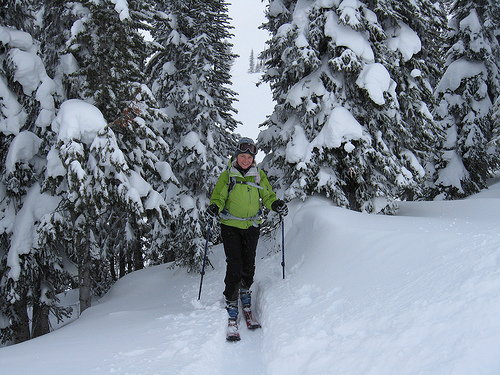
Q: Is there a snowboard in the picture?
A: No, there are no snowboards.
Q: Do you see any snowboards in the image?
A: No, there are no snowboards.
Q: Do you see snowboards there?
A: No, there are no snowboards.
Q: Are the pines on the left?
A: Yes, the pines are on the left of the image.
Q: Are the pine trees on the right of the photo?
A: No, the pine trees are on the left of the image.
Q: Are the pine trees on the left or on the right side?
A: The pine trees are on the left of the image.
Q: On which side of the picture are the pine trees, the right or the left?
A: The pine trees are on the left of the image.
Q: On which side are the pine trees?
A: The pine trees are on the left of the image.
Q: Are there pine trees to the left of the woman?
A: Yes, there are pine trees to the left of the woman.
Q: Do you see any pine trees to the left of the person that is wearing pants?
A: Yes, there are pine trees to the left of the woman.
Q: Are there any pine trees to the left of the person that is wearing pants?
A: Yes, there are pine trees to the left of the woman.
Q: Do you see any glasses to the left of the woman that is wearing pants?
A: No, there are pine trees to the left of the woman.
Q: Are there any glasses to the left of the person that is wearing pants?
A: No, there are pine trees to the left of the woman.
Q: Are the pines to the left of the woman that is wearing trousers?
A: Yes, the pines are to the left of the woman.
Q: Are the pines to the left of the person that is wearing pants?
A: Yes, the pines are to the left of the woman.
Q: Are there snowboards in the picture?
A: No, there are no snowboards.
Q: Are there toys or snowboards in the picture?
A: No, there are no snowboards or toys.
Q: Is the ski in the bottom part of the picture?
A: Yes, the ski is in the bottom of the image.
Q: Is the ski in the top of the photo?
A: No, the ski is in the bottom of the image.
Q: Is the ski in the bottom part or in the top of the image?
A: The ski is in the bottom of the image.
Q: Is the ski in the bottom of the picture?
A: Yes, the ski is in the bottom of the image.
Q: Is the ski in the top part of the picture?
A: No, the ski is in the bottom of the image.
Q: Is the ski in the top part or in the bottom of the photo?
A: The ski is in the bottom of the image.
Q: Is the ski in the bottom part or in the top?
A: The ski is in the bottom of the image.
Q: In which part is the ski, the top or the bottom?
A: The ski is in the bottom of the image.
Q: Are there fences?
A: No, there are no fences.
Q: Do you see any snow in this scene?
A: Yes, there is snow.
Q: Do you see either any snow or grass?
A: Yes, there is snow.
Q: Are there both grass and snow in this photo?
A: No, there is snow but no grass.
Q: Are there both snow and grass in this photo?
A: No, there is snow but no grass.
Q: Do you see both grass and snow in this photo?
A: No, there is snow but no grass.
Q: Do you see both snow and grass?
A: No, there is snow but no grass.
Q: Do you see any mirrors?
A: No, there are no mirrors.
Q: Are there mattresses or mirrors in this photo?
A: No, there are no mirrors or mattresses.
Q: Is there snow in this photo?
A: Yes, there is snow.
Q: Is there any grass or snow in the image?
A: Yes, there is snow.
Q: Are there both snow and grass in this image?
A: No, there is snow but no grass.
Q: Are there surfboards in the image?
A: No, there are no surfboards.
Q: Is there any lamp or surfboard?
A: No, there are no surfboards or lamps.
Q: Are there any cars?
A: No, there are no cars.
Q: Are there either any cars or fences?
A: No, there are no cars or fences.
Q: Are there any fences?
A: No, there are no fences.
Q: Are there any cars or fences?
A: No, there are no fences or cars.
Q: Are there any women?
A: Yes, there is a woman.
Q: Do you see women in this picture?
A: Yes, there is a woman.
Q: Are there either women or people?
A: Yes, there is a woman.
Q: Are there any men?
A: No, there are no men.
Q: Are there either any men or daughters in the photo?
A: No, there are no men or daughters.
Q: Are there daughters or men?
A: No, there are no men or daughters.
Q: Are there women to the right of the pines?
A: Yes, there is a woman to the right of the pines.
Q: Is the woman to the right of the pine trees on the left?
A: Yes, the woman is to the right of the pines.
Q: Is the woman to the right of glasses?
A: No, the woman is to the right of the pines.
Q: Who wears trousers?
A: The woman wears trousers.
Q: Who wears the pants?
A: The woman wears trousers.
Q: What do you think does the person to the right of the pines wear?
A: The woman wears pants.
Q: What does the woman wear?
A: The woman wears pants.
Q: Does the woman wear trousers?
A: Yes, the woman wears trousers.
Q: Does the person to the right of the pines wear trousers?
A: Yes, the woman wears trousers.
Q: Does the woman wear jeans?
A: No, the woman wears trousers.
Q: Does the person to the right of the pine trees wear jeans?
A: No, the woman wears trousers.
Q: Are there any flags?
A: No, there are no flags.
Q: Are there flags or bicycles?
A: No, there are no flags or bicycles.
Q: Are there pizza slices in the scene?
A: No, there are no pizza slices.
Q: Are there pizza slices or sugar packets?
A: No, there are no pizza slices or sugar packets.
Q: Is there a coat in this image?
A: Yes, there is a coat.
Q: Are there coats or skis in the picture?
A: Yes, there is a coat.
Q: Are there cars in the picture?
A: No, there are no cars.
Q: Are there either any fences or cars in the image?
A: No, there are no cars or fences.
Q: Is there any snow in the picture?
A: Yes, there is snow.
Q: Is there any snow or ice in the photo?
A: Yes, there is snow.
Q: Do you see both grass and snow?
A: No, there is snow but no grass.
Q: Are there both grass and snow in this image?
A: No, there is snow but no grass.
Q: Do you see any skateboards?
A: No, there are no skateboards.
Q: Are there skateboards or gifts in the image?
A: No, there are no skateboards or gifts.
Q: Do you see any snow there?
A: Yes, there is snow.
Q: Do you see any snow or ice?
A: Yes, there is snow.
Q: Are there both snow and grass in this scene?
A: No, there is snow but no grass.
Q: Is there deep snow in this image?
A: Yes, there is deep snow.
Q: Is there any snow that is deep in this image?
A: Yes, there is deep snow.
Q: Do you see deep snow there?
A: Yes, there is deep snow.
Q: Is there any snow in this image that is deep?
A: Yes, there is deep snow.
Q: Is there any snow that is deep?
A: Yes, there is snow that is deep.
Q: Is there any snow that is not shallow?
A: Yes, there is deep snow.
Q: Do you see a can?
A: No, there are no cans.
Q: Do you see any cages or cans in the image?
A: No, there are no cans or cages.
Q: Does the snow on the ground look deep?
A: Yes, the snow is deep.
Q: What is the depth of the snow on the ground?
A: The snow is deep.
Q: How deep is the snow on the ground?
A: The snow is deep.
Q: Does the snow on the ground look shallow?
A: No, the snow is deep.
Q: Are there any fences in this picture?
A: No, there are no fences.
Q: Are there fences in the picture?
A: No, there are no fences.